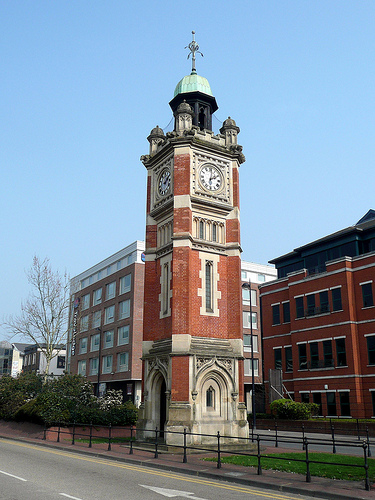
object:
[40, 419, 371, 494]
fence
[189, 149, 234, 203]
clock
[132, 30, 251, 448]
tower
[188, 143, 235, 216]
cement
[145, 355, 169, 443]
doorway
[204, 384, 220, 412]
window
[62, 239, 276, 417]
building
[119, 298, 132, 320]
window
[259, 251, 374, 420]
building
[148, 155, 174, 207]
clock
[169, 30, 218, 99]
pointy top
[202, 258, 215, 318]
window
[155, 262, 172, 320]
window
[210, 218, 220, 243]
window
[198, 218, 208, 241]
window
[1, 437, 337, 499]
edge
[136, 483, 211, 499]
arrow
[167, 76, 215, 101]
roof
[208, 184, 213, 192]
numerals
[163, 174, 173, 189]
hands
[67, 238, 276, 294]
top of building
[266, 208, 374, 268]
roof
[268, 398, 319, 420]
bush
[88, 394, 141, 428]
bush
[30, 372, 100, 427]
bush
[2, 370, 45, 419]
bush